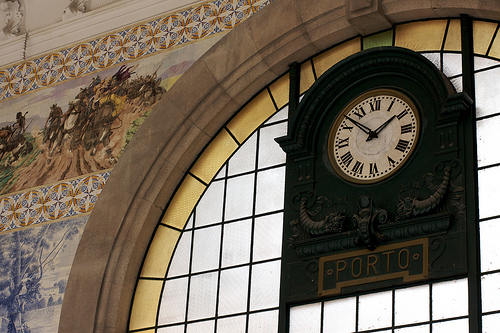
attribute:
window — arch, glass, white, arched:
[66, 1, 500, 332]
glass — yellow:
[227, 91, 274, 139]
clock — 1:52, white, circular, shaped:
[319, 83, 429, 187]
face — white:
[350, 114, 404, 161]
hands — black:
[346, 116, 399, 142]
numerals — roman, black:
[367, 100, 383, 113]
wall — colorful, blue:
[2, 3, 201, 332]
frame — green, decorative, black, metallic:
[274, 43, 479, 305]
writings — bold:
[317, 236, 430, 294]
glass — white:
[225, 167, 260, 221]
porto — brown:
[336, 247, 416, 283]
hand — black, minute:
[345, 114, 374, 142]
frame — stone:
[54, 53, 235, 332]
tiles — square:
[215, 164, 285, 267]